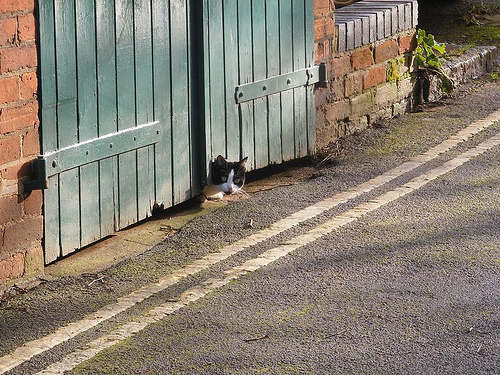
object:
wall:
[316, 1, 424, 149]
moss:
[386, 57, 406, 84]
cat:
[202, 155, 248, 201]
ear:
[236, 156, 250, 168]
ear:
[216, 155, 227, 165]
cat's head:
[210, 155, 248, 193]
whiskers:
[237, 190, 245, 197]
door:
[201, 0, 321, 186]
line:
[0, 109, 499, 370]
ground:
[8, 64, 499, 373]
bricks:
[338, 22, 346, 52]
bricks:
[355, 20, 362, 48]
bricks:
[0, 100, 37, 138]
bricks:
[14, 14, 36, 41]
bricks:
[1, 215, 44, 260]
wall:
[0, 0, 48, 289]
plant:
[407, 29, 455, 94]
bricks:
[384, 9, 392, 38]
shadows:
[144, 190, 206, 217]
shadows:
[17, 158, 35, 203]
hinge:
[32, 156, 48, 190]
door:
[33, 0, 191, 268]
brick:
[327, 55, 352, 80]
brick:
[350, 91, 374, 115]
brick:
[375, 82, 398, 106]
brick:
[1, 43, 38, 68]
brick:
[375, 39, 399, 63]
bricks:
[0, 131, 22, 163]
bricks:
[369, 14, 376, 43]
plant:
[408, 28, 451, 94]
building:
[0, 2, 428, 295]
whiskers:
[240, 188, 250, 197]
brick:
[390, 56, 410, 80]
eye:
[221, 176, 228, 181]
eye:
[234, 177, 241, 183]